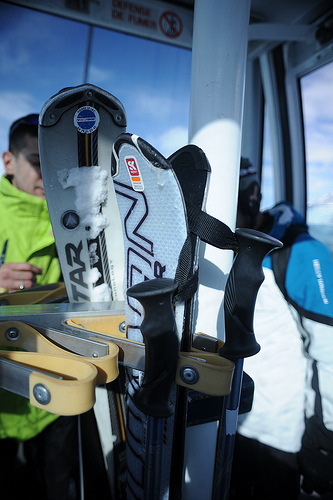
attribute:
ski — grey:
[89, 300, 133, 324]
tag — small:
[70, 103, 100, 139]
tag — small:
[81, 107, 95, 128]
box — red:
[127, 155, 139, 176]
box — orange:
[130, 173, 144, 181]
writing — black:
[114, 187, 164, 489]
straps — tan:
[8, 315, 129, 409]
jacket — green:
[0, 173, 84, 451]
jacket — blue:
[268, 205, 332, 320]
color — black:
[1, 409, 114, 497]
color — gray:
[179, 419, 220, 498]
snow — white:
[58, 164, 111, 297]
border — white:
[71, 105, 100, 134]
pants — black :
[8, 408, 109, 490]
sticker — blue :
[121, 152, 150, 192]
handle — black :
[131, 273, 200, 417]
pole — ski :
[111, 260, 254, 468]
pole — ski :
[120, 246, 256, 489]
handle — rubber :
[124, 270, 190, 414]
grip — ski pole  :
[123, 282, 210, 422]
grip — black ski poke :
[121, 274, 186, 401]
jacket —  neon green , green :
[1, 165, 126, 445]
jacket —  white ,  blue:
[189, 173, 319, 459]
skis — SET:
[110, 127, 210, 466]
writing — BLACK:
[116, 165, 166, 419]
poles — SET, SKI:
[121, 220, 283, 487]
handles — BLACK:
[125, 224, 288, 411]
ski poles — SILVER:
[116, 219, 290, 487]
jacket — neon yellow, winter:
[3, 171, 61, 438]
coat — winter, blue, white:
[238, 199, 322, 462]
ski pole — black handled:
[124, 274, 181, 487]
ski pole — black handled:
[213, 225, 284, 468]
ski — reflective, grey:
[32, 77, 127, 437]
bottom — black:
[168, 140, 209, 237]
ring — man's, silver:
[18, 280, 24, 291]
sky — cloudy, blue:
[9, 20, 188, 81]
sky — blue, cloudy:
[297, 70, 322, 226]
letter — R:
[62, 237, 86, 267]